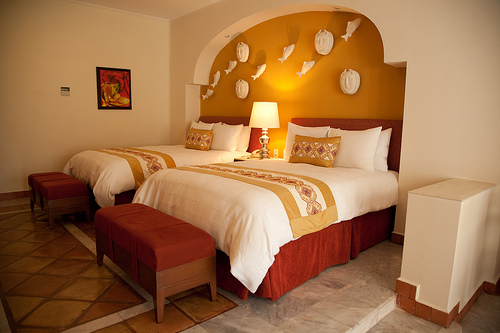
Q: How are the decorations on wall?
A: Ocean themed.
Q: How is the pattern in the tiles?
A: Diamond.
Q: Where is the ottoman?
A: End of bed.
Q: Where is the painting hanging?
A: On the wall.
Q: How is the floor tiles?
A: Orange and brown.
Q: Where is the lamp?
A: Between the beds.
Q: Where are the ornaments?
A: Above the bed.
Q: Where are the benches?
A: In front of the beds.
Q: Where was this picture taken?
A: Hotel room.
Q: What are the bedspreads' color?
A: White.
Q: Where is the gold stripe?
A: On the bedspreads.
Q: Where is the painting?
A: On the wall.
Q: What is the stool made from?
A: Wood.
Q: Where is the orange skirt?
A: Bottom of the bed.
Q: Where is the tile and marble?
A: On the floor.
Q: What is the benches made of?
A: Wood and cushion.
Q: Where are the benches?
A: Foot of beds.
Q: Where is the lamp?
A: Between beds.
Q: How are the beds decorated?
A: Cream,gold and red comforter.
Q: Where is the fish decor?
A: Wall above bed.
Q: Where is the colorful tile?
A: Floor at foot of bed.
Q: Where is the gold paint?
A: Wall behind bed.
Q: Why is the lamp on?
A: Light room.